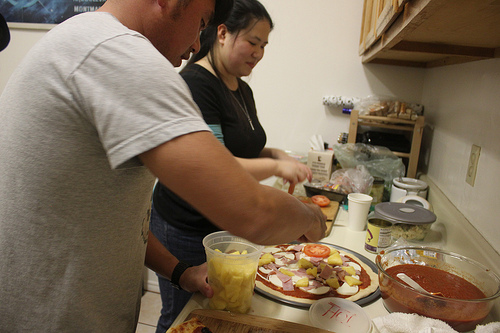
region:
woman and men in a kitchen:
[3, 5, 488, 327]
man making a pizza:
[0, 0, 381, 324]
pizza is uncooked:
[252, 234, 385, 311]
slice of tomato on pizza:
[300, 237, 336, 262]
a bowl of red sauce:
[373, 233, 499, 322]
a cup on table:
[341, 183, 375, 233]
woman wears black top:
[196, 2, 287, 152]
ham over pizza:
[254, 237, 381, 308]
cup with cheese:
[192, 225, 264, 320]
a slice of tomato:
[308, 186, 331, 211]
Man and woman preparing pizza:
[0, 0, 383, 332]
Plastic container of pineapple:
[201, 221, 262, 331]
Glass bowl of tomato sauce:
[369, 245, 497, 331]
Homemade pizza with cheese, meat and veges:
[240, 228, 392, 313]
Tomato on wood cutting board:
[283, 177, 341, 248]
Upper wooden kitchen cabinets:
[319, 1, 494, 82]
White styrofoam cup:
[344, 185, 372, 256]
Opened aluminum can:
[356, 215, 398, 261]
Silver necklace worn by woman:
[209, 1, 284, 160]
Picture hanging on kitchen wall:
[1, 0, 136, 39]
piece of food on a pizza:
[302, 241, 330, 257]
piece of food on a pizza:
[292, 272, 312, 291]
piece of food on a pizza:
[325, 273, 339, 290]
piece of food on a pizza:
[342, 274, 363, 288]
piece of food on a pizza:
[334, 282, 359, 297]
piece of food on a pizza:
[317, 262, 332, 283]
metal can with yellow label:
[361, 213, 396, 260]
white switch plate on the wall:
[459, 142, 481, 190]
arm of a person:
[86, 32, 338, 254]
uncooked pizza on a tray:
[243, 239, 385, 314]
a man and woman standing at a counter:
[138, 3, 330, 331]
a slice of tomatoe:
[295, 238, 338, 262]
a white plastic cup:
[335, 192, 377, 234]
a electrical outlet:
[462, 137, 489, 190]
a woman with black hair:
[218, 14, 283, 59]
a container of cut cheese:
[197, 240, 272, 315]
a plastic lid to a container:
[298, 288, 375, 332]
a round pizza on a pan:
[248, 245, 375, 313]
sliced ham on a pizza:
[267, 261, 304, 306]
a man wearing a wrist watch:
[171, 253, 196, 285]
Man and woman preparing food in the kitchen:
[1, 0, 331, 332]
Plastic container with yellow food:
[202, 226, 262, 320]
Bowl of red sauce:
[375, 243, 498, 322]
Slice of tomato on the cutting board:
[313, 191, 331, 209]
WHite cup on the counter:
[346, 188, 370, 240]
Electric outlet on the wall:
[461, 141, 483, 186]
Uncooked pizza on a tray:
[250, 242, 382, 309]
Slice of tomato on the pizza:
[301, 240, 329, 258]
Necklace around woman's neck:
[216, 62, 258, 135]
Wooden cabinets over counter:
[362, 0, 497, 65]